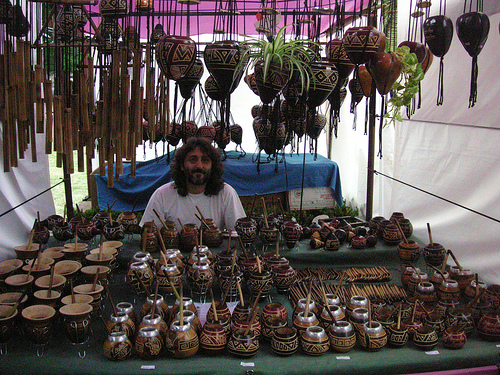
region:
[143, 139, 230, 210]
this is a man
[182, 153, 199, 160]
the man is light skinned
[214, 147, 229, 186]
this is the hair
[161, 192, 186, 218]
this is a t shirt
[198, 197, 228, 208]
the t shirt is white in color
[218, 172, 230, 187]
the hair is long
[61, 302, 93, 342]
this is a pot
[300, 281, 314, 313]
this is a stick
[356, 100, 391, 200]
this is a pole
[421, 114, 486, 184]
this is the wall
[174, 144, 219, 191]
the man has beard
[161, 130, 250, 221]
the man has beard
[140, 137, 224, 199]
the man has beard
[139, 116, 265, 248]
man sitting behind the stall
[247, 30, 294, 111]
a plant in a pot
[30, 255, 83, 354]
some curved cool bowls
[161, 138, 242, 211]
some cool a old guy with a white shirt on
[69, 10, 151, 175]
some cool wood bells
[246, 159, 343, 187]
one blue tarp on a table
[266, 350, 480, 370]
white stickers on the tables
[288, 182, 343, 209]
a white box under the tabel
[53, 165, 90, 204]
some bad growing grass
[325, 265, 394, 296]
some wood smashers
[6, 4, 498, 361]
A man surrounded by lots of pottery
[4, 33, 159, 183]
Hanging bamboo chimes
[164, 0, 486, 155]
Pots hanging in macrame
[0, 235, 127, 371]
Fancy goblets on a table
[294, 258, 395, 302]
Incense sticks on a table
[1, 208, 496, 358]
Various pots holding incense sticks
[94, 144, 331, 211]
A large blue tarp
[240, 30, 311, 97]
A spider plant hanging from a pot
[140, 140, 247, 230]
A man sitting at a table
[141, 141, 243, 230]
A man with long dark hair wearing a white tee shirt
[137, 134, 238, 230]
A man in a white shirt.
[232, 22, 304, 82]
A green fern in a pot.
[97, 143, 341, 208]
A blue sheet covering a table.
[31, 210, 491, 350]
A table covered in pots.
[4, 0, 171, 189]
A group of hanging wind chimes.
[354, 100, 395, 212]
A wooden tent pole.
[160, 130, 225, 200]
A man with long curly hair.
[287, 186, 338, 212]
A white box on grass.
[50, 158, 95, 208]
A door on a tent.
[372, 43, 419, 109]
A red hanging pot with a plant.